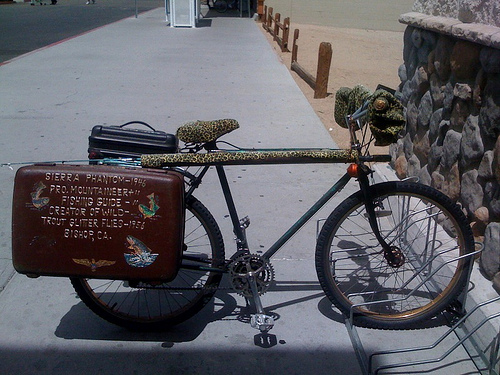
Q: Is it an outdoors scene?
A: Yes, it is outdoors.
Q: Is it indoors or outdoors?
A: It is outdoors.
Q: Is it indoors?
A: No, it is outdoors.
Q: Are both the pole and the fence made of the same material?
A: Yes, both the pole and the fence are made of wood.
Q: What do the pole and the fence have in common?
A: The material, both the pole and the fence are wooden.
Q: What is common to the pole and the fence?
A: The material, both the pole and the fence are wooden.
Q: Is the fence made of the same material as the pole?
A: Yes, both the fence and the pole are made of wood.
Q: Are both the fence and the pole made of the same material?
A: Yes, both the fence and the pole are made of wood.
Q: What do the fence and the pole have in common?
A: The material, both the fence and the pole are wooden.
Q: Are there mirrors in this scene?
A: No, there are no mirrors.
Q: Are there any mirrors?
A: No, there are no mirrors.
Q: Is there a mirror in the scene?
A: No, there are no mirrors.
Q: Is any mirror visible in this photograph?
A: No, there are no mirrors.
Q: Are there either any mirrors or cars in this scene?
A: No, there are no mirrors or cars.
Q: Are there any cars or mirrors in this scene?
A: No, there are no mirrors or cars.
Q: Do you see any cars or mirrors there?
A: No, there are no mirrors or cars.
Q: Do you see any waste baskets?
A: No, there are no waste baskets.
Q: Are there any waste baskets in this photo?
A: No, there are no waste baskets.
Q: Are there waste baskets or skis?
A: No, there are no waste baskets or skis.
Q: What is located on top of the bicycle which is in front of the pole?
A: The seat is on top of the bicycle.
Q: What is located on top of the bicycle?
A: The seat is on top of the bicycle.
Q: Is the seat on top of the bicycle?
A: Yes, the seat is on top of the bicycle.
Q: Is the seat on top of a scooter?
A: No, the seat is on top of the bicycle.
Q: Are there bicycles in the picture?
A: Yes, there is a bicycle.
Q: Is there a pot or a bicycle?
A: Yes, there is a bicycle.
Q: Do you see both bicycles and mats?
A: No, there is a bicycle but no mats.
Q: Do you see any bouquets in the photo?
A: No, there are no bouquets.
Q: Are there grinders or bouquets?
A: No, there are no bouquets or grinders.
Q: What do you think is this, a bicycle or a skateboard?
A: This is a bicycle.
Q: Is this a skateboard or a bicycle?
A: This is a bicycle.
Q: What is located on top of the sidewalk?
A: The bicycle is on top of the sidewalk.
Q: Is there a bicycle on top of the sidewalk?
A: Yes, there is a bicycle on top of the sidewalk.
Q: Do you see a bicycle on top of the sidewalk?
A: Yes, there is a bicycle on top of the sidewalk.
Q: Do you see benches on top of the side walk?
A: No, there is a bicycle on top of the side walk.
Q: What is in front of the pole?
A: The bicycle is in front of the pole.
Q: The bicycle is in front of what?
A: The bicycle is in front of the pole.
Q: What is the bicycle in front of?
A: The bicycle is in front of the pole.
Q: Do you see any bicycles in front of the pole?
A: Yes, there is a bicycle in front of the pole.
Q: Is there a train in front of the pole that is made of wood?
A: No, there is a bicycle in front of the pole.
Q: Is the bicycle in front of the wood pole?
A: Yes, the bicycle is in front of the pole.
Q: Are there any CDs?
A: No, there are no cds.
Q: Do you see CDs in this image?
A: No, there are no cds.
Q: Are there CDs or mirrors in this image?
A: No, there are no CDs or mirrors.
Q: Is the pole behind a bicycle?
A: Yes, the pole is behind a bicycle.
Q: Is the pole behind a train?
A: No, the pole is behind a bicycle.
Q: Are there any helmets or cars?
A: No, there are no cars or helmets.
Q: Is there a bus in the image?
A: No, there are no buses.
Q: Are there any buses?
A: No, there are no buses.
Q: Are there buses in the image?
A: No, there are no buses.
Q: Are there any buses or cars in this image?
A: No, there are no buses or cars.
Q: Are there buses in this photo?
A: No, there are no buses.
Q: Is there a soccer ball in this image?
A: No, there are no soccer balls.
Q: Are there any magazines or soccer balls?
A: No, there are no soccer balls or magazines.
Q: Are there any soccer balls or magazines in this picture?
A: No, there are no soccer balls or magazines.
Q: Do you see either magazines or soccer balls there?
A: No, there are no soccer balls or magazines.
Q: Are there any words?
A: Yes, there are words.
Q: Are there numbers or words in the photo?
A: Yes, there are words.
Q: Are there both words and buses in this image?
A: No, there are words but no buses.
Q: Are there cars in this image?
A: No, there are no cars.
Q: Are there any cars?
A: No, there are no cars.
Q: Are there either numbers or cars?
A: No, there are no cars or numbers.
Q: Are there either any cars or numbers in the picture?
A: No, there are no cars or numbers.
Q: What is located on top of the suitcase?
A: The words are on top of the suitcase.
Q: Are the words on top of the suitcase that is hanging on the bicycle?
A: Yes, the words are on top of the suitcase.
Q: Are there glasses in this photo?
A: No, there are no glasses.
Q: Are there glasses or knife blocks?
A: No, there are no glasses or knife blocks.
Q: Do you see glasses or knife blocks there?
A: No, there are no glasses or knife blocks.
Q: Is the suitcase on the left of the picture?
A: Yes, the suitcase is on the left of the image.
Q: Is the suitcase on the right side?
A: No, the suitcase is on the left of the image.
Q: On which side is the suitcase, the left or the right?
A: The suitcase is on the left of the image.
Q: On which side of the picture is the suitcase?
A: The suitcase is on the left of the image.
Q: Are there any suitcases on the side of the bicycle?
A: Yes, there is a suitcase on the side of the bicycle.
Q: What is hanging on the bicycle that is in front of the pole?
A: The suitcase is hanging on the bicycle.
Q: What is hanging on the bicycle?
A: The suitcase is hanging on the bicycle.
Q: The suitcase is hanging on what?
A: The suitcase is hanging on the bicycle.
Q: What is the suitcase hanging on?
A: The suitcase is hanging on the bicycle.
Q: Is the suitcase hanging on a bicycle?
A: Yes, the suitcase is hanging on a bicycle.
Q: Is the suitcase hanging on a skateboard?
A: No, the suitcase is hanging on a bicycle.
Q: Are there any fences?
A: Yes, there is a fence.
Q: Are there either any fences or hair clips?
A: Yes, there is a fence.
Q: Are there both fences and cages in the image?
A: No, there is a fence but no cages.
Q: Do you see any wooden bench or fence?
A: Yes, there is a wood fence.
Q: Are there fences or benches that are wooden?
A: Yes, the fence is wooden.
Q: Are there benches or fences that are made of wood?
A: Yes, the fence is made of wood.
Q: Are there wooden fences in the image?
A: Yes, there is a wood fence.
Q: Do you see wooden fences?
A: Yes, there is a wood fence.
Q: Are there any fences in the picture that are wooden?
A: Yes, there is a fence that is wooden.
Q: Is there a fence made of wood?
A: Yes, there is a fence that is made of wood.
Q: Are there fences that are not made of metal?
A: Yes, there is a fence that is made of wood.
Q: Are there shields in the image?
A: No, there are no shields.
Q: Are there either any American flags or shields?
A: No, there are no shields or American flags.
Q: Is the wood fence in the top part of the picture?
A: Yes, the fence is in the top of the image.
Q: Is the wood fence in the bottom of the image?
A: No, the fence is in the top of the image.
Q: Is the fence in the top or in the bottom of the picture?
A: The fence is in the top of the image.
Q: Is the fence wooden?
A: Yes, the fence is wooden.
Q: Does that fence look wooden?
A: Yes, the fence is wooden.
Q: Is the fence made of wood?
A: Yes, the fence is made of wood.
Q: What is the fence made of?
A: The fence is made of wood.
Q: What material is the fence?
A: The fence is made of wood.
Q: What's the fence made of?
A: The fence is made of wood.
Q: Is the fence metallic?
A: No, the fence is wooden.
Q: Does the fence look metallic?
A: No, the fence is wooden.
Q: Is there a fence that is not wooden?
A: No, there is a fence but it is wooden.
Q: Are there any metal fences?
A: No, there is a fence but it is made of wood.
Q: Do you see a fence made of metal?
A: No, there is a fence but it is made of wood.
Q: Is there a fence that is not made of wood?
A: No, there is a fence but it is made of wood.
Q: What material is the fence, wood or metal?
A: The fence is made of wood.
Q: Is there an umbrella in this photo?
A: No, there are no umbrellas.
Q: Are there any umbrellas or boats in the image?
A: No, there are no umbrellas or boats.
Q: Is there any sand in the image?
A: Yes, there is sand.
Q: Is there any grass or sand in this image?
A: Yes, there is sand.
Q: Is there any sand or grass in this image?
A: Yes, there is sand.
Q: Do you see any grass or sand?
A: Yes, there is sand.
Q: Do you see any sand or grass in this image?
A: Yes, there is sand.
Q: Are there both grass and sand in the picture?
A: No, there is sand but no grass.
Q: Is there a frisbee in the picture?
A: No, there are no frisbees.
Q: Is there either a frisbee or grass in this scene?
A: No, there are no frisbees or grass.